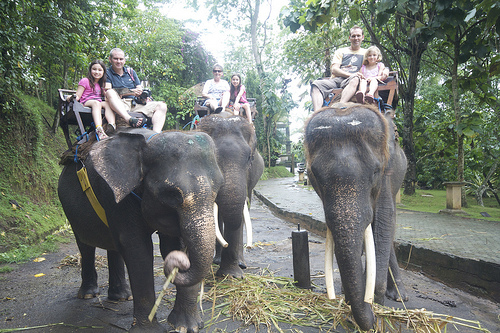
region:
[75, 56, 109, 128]
A person seated on an elephant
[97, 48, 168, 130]
A person seated on an elephant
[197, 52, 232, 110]
A person seated on an elephant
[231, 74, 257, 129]
A person seated on an elephant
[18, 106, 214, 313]
A big black elephant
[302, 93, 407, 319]
A big black elephant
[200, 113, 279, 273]
A big black elephant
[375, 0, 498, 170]
green trees by the roadside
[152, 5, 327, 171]
bright sky between trees and mountain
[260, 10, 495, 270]
trees and grass within elevated tiled border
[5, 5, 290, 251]
trees and plants on wall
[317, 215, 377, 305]
long white tusks with blunt ends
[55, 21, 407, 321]
passengers in benches on top of elephants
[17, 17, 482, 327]
elephants walking down paved pathway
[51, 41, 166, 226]
slanting bench strapped around elephant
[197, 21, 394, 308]
adults and children smiling during ride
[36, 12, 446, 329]
many people are sitting in the elephant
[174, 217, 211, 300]
trunk of the elephant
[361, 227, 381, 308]
tusk of the elephant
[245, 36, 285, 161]
tree with leaves and branches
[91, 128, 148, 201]
ear of the elephant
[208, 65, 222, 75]
a person wearing goggles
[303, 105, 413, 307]
black color big elephant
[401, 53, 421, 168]
trunk of the tree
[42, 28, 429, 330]
Pairs of people riding elephants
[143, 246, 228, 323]
The left elephant is grasping a stick in it's trunk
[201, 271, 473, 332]
Straw scattered on paved path.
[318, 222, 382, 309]
The elephant's tusks have been cut short.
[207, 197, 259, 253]
The tusks on this elephant have been trimmed.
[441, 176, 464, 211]
Cement garbage can along sidewalk path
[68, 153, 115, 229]
Brown strap holding seat on the back of elephant.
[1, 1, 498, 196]
Green shady trees are planted on both sides of street.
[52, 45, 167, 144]
The people are sitting on a wooden bench strapped to the back of the elephant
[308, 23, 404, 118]
Man and his daughter sitting on elephant back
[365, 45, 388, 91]
A little girl on an elephant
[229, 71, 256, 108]
A little girl on an elephant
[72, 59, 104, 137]
A little girl on an elephant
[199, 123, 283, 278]
A big black elephant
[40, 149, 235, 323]
A big black elephant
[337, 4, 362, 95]
A man seated on an elephant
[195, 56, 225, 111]
A man seated on an elephant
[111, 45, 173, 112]
A man seated on an elephant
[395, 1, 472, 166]
green tree on the roadside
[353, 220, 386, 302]
tusk of the elephant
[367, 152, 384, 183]
eye of the elephant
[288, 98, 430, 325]
a large grey elephant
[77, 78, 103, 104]
shirt is pink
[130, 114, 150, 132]
sandal is black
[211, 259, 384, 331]
some green and yellow weeds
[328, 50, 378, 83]
shirt is yellow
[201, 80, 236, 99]
shirt is white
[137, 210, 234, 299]
trunk of the elephant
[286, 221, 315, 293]
small pole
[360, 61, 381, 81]
shirt is pink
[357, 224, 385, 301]
tusk is white and stron g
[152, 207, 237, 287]
trunk of the elephant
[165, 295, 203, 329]
foot of the elephant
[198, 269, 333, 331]
green weeds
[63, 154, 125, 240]
a yellow strap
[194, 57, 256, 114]
two people on the elephant